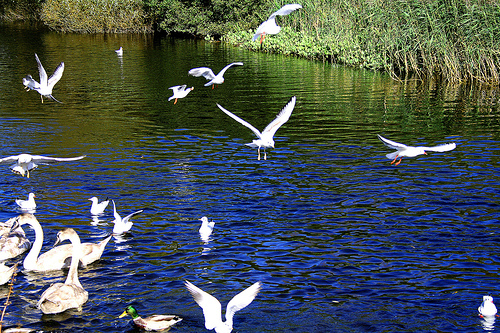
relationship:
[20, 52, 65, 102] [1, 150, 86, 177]
bird next to bird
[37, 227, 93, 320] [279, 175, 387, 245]
bird sitting in water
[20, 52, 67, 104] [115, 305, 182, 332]
bird swimming beside bird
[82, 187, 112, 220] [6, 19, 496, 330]
bird swimming on water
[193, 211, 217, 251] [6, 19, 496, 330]
bird swimming on water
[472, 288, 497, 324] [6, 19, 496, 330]
bird swimming on water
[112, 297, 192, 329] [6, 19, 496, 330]
bird swimming on water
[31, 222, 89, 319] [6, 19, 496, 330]
bird swimming on water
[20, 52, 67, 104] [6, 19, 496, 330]
bird swimming on water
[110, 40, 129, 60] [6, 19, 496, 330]
bird swimming on water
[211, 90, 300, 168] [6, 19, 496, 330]
bird flying near water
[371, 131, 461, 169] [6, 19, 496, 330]
birds flying near water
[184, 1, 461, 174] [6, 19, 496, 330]
birds flying over water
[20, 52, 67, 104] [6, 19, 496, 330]
bird flying over water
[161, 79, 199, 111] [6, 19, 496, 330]
bird flying over water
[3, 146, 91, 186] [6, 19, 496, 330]
bird flying over water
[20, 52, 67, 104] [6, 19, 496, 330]
bird swimming in water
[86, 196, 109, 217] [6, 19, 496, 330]
bird swimming in water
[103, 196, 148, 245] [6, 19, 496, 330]
bird swimming in water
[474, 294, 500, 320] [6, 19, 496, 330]
bird swimming in water